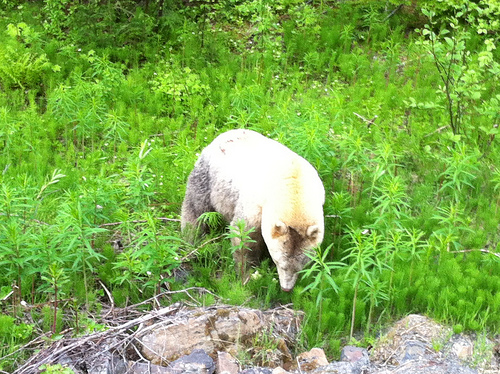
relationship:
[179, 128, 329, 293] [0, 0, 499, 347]
bear in grass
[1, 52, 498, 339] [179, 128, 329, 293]
tall grass next to bear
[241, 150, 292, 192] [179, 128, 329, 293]
fur on bear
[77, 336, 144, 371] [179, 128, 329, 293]
rock next to bear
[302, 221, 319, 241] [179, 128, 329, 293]
ear of bear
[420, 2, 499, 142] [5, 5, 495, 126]
tree in forest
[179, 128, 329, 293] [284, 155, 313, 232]
bear with stripe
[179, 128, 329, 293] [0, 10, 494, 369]
bear between plants